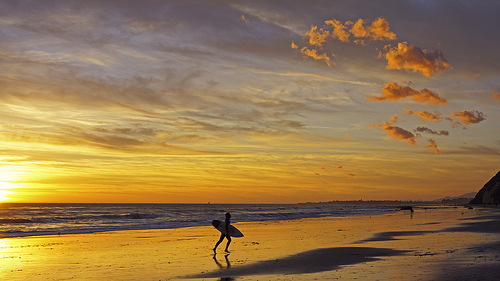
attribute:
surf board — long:
[208, 216, 247, 239]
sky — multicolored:
[0, 4, 499, 174]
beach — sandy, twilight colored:
[0, 212, 498, 276]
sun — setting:
[0, 152, 39, 202]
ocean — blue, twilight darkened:
[3, 202, 203, 225]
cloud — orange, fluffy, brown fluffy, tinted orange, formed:
[383, 40, 457, 78]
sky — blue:
[215, 22, 268, 37]